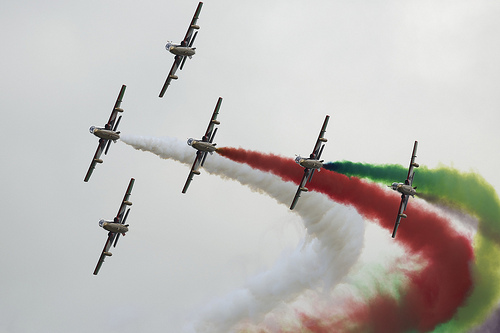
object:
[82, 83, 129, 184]
plane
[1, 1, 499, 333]
sky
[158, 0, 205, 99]
plane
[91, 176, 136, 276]
plane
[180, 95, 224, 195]
plane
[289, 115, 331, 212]
plane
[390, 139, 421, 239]
plane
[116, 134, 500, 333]
smoke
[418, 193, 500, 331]
smoke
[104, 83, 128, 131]
wing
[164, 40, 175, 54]
propeller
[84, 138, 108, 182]
wing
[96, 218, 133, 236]
body